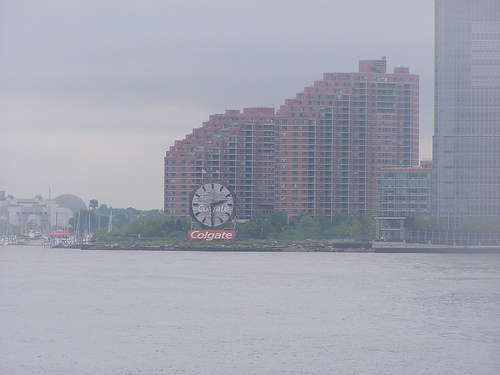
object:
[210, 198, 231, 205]
hour hand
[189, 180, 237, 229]
clock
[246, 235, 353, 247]
grass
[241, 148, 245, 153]
window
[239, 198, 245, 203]
window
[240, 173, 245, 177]
window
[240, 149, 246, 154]
window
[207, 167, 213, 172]
window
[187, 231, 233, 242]
sign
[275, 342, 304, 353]
ripples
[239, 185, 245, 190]
window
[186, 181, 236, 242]
colgate clock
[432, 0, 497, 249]
skyscraper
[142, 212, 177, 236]
trees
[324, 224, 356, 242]
tree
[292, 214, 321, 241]
tree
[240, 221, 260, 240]
tree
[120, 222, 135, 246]
tree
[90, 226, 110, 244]
tree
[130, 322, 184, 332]
ripple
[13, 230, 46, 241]
boat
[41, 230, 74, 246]
boat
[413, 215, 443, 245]
trees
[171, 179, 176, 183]
window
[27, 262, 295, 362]
ripples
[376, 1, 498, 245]
building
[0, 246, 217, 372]
ripples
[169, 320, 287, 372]
ripples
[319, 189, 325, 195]
windows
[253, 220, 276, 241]
trees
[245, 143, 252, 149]
building window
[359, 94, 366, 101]
building window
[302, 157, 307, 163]
building window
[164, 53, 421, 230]
building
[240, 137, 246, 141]
window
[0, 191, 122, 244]
building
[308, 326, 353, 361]
ripples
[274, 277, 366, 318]
ripples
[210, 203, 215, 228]
hands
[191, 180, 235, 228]
face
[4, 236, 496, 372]
harbor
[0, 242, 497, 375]
water